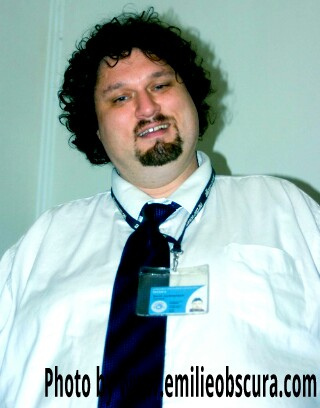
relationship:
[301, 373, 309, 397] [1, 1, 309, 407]
letter printed on picture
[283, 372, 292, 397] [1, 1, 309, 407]
letter printed on picture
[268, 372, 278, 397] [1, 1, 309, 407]
letter printed on picture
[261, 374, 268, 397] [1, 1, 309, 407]
letter printed on picture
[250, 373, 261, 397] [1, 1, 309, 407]
letter printed on picture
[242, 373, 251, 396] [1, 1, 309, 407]
letter printed on picture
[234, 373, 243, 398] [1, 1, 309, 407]
letter printed on picture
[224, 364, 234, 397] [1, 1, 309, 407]
letter printed on picture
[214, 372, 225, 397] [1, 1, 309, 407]
letter printed on picture